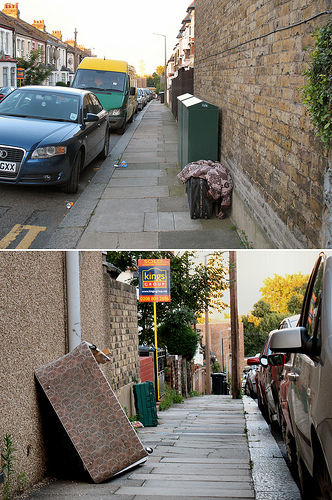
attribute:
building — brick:
[193, 14, 329, 236]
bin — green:
[132, 379, 158, 426]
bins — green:
[170, 89, 226, 181]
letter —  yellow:
[143, 258, 147, 265]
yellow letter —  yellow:
[79, 52, 136, 78]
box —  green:
[124, 373, 161, 430]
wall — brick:
[192, 0, 330, 249]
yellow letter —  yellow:
[156, 273, 159, 282]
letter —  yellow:
[144, 257, 155, 266]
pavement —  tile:
[135, 87, 194, 240]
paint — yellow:
[1, 221, 38, 249]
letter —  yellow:
[159, 272, 165, 281]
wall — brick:
[219, 31, 300, 139]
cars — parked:
[32, 60, 172, 178]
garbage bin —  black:
[176, 91, 228, 177]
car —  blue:
[1, 85, 110, 194]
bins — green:
[166, 86, 230, 178]